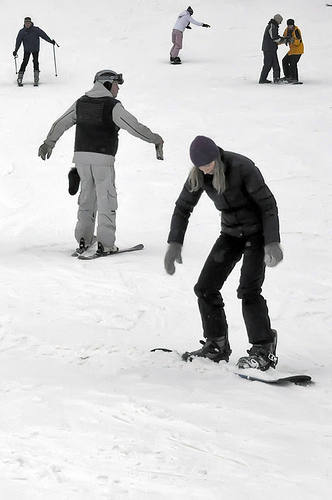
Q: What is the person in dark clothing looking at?
A: Her feet.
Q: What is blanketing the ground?
A: Snow.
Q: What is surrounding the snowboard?
A: Snow.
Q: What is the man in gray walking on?
A: Skis.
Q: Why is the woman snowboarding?
A: To get down the slope.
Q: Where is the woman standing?
A: On her snow-covered snowboard.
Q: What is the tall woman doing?
A: Snowboarding.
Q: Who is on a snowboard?
A: A tall and skinny woman.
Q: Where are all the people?
A: On the snow.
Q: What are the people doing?
A: Skiing and snowboarding.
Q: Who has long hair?
A: A woman.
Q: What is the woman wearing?
A: A beanie.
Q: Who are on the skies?
A: A person.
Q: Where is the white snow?
A: On the ground.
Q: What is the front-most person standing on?
A: Snowboard.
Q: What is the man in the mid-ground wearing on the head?
A: Hat.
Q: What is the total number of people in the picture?
A: 6.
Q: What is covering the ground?
A: Snow.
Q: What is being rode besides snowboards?
A: Skis.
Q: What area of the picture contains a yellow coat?
A: Upper right.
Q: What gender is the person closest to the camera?
A: Female.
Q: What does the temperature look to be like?
A: Cold.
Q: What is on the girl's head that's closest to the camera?
A: A beanie.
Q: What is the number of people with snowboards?
A: 3.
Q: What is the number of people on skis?
A: 2.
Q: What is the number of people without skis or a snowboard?
A: 1.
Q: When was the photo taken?
A: During the day.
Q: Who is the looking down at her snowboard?
A: A lady.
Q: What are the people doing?
A: Skiing.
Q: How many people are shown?
A: Six.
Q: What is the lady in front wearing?
A: Black and grey.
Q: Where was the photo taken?
A: Ski slope.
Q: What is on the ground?
A: Snow.